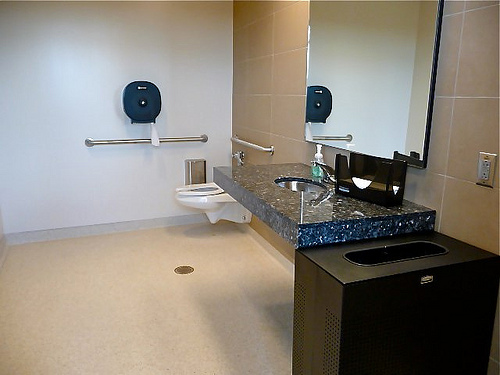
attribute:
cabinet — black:
[291, 229, 498, 374]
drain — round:
[167, 258, 202, 281]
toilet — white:
[173, 165, 233, 217]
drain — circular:
[174, 265, 194, 275]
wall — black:
[191, 113, 216, 146]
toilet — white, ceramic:
[172, 181, 252, 228]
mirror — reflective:
[285, 23, 445, 172]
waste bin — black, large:
[286, 221, 499, 374]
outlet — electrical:
[459, 136, 497, 200]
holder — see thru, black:
[121, 80, 163, 127]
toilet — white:
[173, 181, 253, 224]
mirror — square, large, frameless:
[305, 1, 444, 168]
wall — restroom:
[231, 1, 498, 267]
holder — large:
[334, 150, 407, 209]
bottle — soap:
[307, 142, 332, 179]